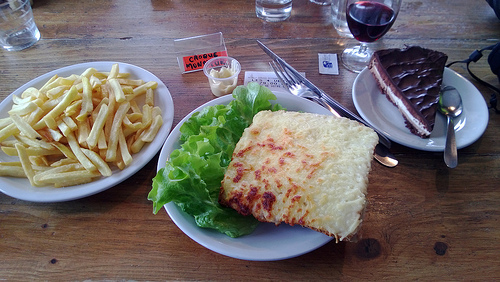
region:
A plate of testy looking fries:
[15, 84, 130, 187]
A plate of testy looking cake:
[189, 104, 354, 240]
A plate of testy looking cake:
[372, 49, 465, 136]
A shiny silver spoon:
[444, 83, 457, 168]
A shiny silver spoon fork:
[273, 69, 307, 94]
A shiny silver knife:
[320, 89, 385, 139]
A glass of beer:
[346, 0, 372, 62]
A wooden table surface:
[393, 202, 442, 280]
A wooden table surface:
[49, 213, 154, 275]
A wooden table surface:
[65, 4, 153, 66]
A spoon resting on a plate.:
[433, 80, 465, 171]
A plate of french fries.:
[0, 58, 177, 204]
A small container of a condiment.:
[198, 52, 243, 96]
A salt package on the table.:
[313, 49, 340, 76]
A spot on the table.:
[43, 255, 63, 267]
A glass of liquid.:
[337, 0, 402, 75]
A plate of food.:
[146, 81, 381, 262]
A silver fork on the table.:
[271, 55, 400, 170]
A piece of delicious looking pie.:
[366, 45, 451, 142]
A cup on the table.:
[1, 0, 43, 52]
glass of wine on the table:
[345, 12, 375, 44]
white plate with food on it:
[249, 247, 289, 274]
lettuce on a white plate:
[142, 180, 187, 216]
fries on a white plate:
[76, 162, 116, 202]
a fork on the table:
[273, 63, 302, 94]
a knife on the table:
[265, 37, 290, 67]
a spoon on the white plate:
[451, 103, 477, 129]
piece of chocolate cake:
[406, 95, 439, 140]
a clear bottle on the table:
[25, 22, 61, 58]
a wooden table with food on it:
[87, 243, 132, 279]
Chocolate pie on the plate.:
[365, 40, 446, 137]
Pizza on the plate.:
[213, 103, 379, 242]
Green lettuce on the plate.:
[147, 81, 283, 240]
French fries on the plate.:
[2, 65, 163, 195]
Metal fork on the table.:
[256, 37, 400, 173]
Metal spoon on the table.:
[433, 76, 461, 170]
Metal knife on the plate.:
[255, 34, 384, 151]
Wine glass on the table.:
[342, 1, 400, 73]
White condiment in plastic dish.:
[204, 55, 239, 93]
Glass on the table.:
[0, 0, 45, 56]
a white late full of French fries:
[0, 60, 169, 202]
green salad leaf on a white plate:
[148, 85, 278, 242]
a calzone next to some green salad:
[219, 110, 379, 249]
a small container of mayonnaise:
[203, 55, 242, 95]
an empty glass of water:
[0, 0, 40, 50]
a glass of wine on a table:
[343, 0, 400, 77]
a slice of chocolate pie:
[368, 48, 448, 138]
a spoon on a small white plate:
[438, 85, 463, 170]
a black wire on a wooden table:
[447, 39, 499, 89]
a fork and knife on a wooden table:
[255, 42, 400, 167]